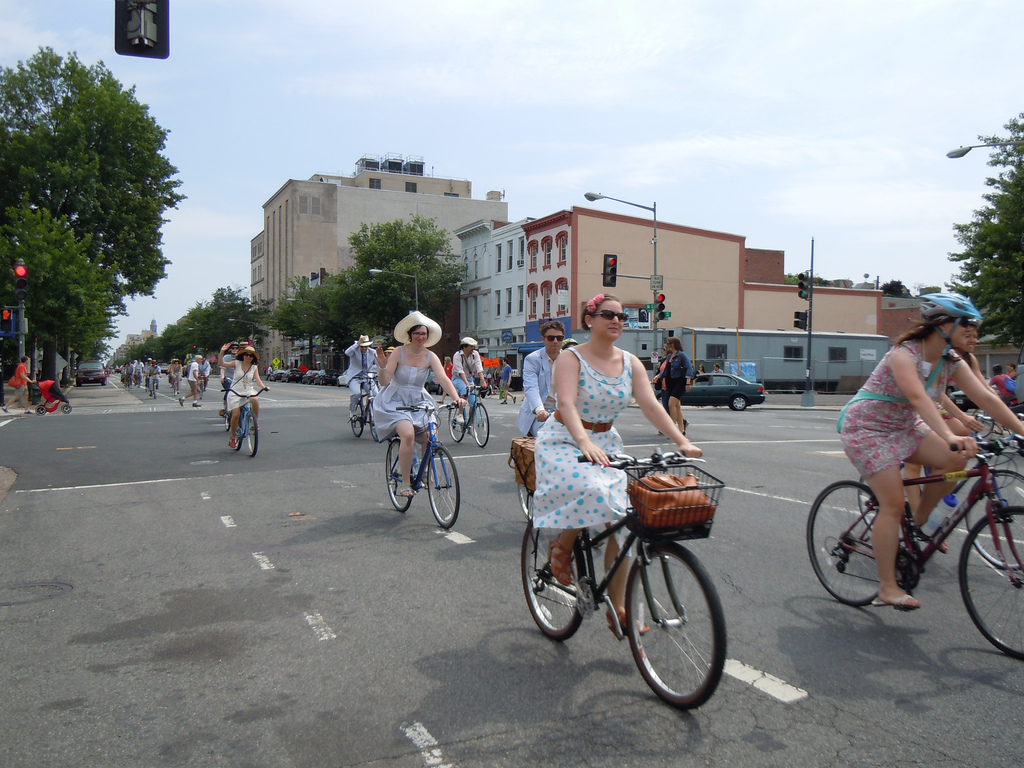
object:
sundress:
[532, 347, 633, 556]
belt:
[553, 409, 613, 431]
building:
[452, 205, 1024, 393]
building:
[249, 153, 509, 376]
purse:
[629, 471, 717, 527]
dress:
[840, 337, 964, 480]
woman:
[837, 292, 1024, 609]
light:
[113, 0, 170, 60]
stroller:
[33, 378, 72, 416]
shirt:
[16, 363, 29, 385]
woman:
[2, 356, 38, 414]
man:
[517, 320, 567, 437]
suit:
[339, 341, 382, 412]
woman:
[532, 293, 704, 633]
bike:
[507, 436, 728, 710]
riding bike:
[373, 401, 460, 529]